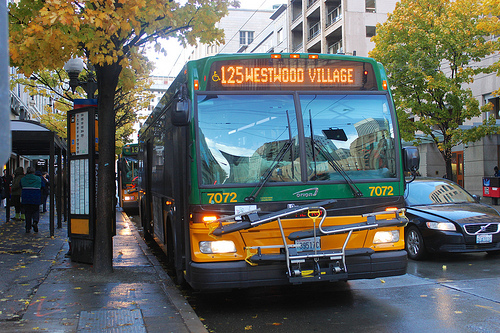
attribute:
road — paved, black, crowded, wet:
[418, 255, 489, 331]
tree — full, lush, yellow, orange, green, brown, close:
[392, 18, 478, 128]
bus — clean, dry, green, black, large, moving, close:
[138, 53, 410, 286]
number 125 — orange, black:
[220, 64, 245, 87]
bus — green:
[136, 45, 417, 301]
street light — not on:
[65, 53, 88, 98]